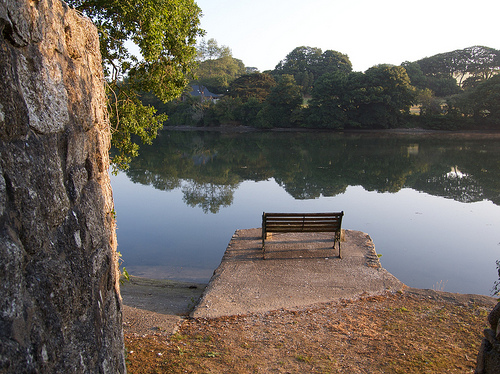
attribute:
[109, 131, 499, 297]
water — calm, lake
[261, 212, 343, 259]
bench — wooden, small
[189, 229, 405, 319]
concrete surface — small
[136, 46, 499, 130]
trees — far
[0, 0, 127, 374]
tree bark — gray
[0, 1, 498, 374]
picture — clear, daytime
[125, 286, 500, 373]
ground — grassy, bare, dirt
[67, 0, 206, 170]
tree — green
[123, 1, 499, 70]
sky — clear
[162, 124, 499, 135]
shore — dirt